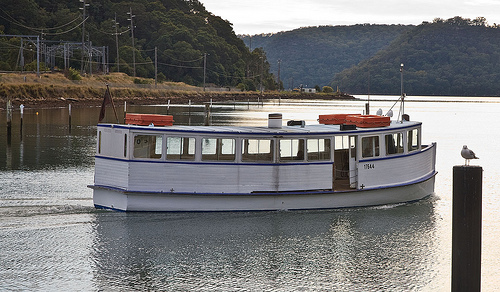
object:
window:
[134, 135, 162, 160]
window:
[279, 135, 306, 164]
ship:
[88, 64, 438, 226]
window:
[240, 135, 276, 163]